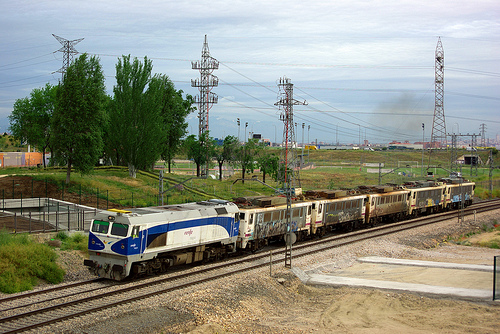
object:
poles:
[276, 76, 301, 271]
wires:
[215, 55, 419, 144]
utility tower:
[475, 120, 489, 153]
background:
[1, 0, 500, 170]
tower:
[428, 33, 451, 148]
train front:
[79, 196, 242, 288]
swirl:
[108, 214, 242, 257]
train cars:
[236, 179, 482, 249]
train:
[81, 173, 479, 282]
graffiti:
[238, 172, 477, 251]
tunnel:
[0, 193, 116, 229]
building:
[0, 149, 55, 170]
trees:
[104, 54, 180, 184]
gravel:
[0, 201, 498, 332]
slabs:
[299, 268, 500, 305]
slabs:
[352, 254, 500, 272]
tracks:
[0, 199, 500, 323]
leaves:
[14, 101, 52, 121]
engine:
[82, 196, 242, 281]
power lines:
[0, 96, 500, 122]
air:
[2, 36, 34, 50]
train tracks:
[0, 192, 500, 332]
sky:
[2, 0, 499, 32]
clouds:
[0, 0, 498, 33]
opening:
[0, 172, 108, 238]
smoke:
[367, 89, 437, 142]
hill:
[0, 163, 261, 208]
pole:
[288, 180, 294, 268]